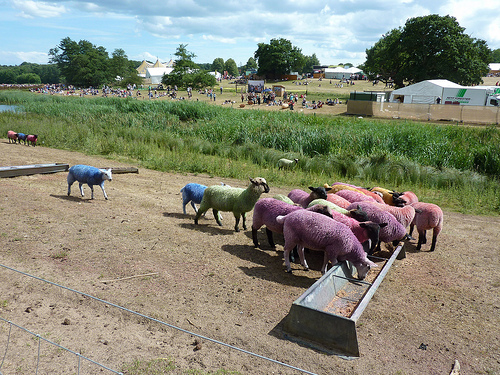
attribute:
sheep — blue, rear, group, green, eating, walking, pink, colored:
[52, 169, 109, 200]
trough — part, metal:
[298, 278, 409, 311]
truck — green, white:
[313, 79, 387, 104]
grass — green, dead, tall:
[48, 110, 137, 135]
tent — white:
[143, 68, 175, 86]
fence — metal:
[258, 96, 364, 122]